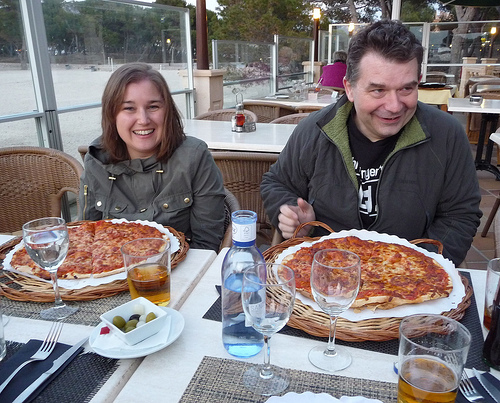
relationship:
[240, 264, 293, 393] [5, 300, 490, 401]
clear glass on table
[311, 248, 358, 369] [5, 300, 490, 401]
clear glass on table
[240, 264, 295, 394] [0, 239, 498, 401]
clear glass on table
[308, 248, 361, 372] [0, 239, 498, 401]
clear glass on table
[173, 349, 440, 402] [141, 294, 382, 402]
placemat on table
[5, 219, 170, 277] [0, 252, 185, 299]
pizza in basket tray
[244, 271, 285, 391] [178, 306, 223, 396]
glass on table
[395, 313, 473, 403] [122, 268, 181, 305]
glass of beer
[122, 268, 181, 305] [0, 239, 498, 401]
beer on table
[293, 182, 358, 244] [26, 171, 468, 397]
fork on table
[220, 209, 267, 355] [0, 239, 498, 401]
bottle on table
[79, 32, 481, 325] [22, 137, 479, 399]
couple at table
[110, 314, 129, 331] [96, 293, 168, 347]
olive in dish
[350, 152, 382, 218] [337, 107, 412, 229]
design on black shirt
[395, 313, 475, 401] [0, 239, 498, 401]
glass on table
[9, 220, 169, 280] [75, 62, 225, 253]
pizza in front of girl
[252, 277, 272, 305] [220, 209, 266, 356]
edge of bottle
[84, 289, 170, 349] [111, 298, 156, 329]
bowl of olives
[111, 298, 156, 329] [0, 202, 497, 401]
olives on table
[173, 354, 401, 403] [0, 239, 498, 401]
placemat on table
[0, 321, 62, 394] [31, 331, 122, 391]
fork and knife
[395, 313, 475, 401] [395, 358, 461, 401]
glass of beer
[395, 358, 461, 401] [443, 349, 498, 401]
beer next to silverware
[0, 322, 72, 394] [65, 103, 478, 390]
fork on table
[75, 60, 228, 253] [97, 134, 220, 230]
girl in jacket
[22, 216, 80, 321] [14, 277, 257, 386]
boys on table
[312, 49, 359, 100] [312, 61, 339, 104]
person in jacket